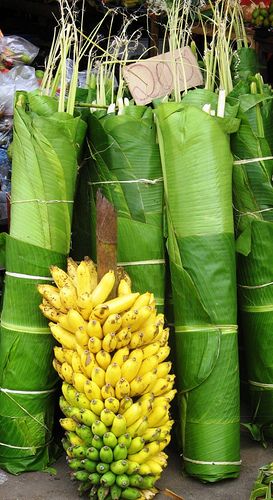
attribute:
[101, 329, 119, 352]
yellow banana — ripe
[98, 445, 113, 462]
banana — green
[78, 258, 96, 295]
banana — green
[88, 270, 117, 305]
banana — green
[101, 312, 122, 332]
banana — green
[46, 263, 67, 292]
banana — green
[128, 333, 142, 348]
banana — yellow, ripe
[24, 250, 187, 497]
banana — ripe, yellow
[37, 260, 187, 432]
bananas — yellow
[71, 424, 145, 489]
banana — not ripe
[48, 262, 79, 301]
banana — yellow, ripe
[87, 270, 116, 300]
yellow banana — ripe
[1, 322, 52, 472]
banana leaf — rolled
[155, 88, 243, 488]
banana leaf — rolled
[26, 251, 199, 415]
banana — ripe, yellow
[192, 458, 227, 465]
rope — white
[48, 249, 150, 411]
banana — ripe, yellow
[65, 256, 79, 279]
yellow banana — ripe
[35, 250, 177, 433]
banana — ripe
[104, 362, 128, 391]
banana — yellow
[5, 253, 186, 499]
banana — yellow, ripe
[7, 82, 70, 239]
banana leaves — fresh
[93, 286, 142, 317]
banana — yellow, ripe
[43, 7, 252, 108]
shuts — banana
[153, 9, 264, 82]
table — wooden